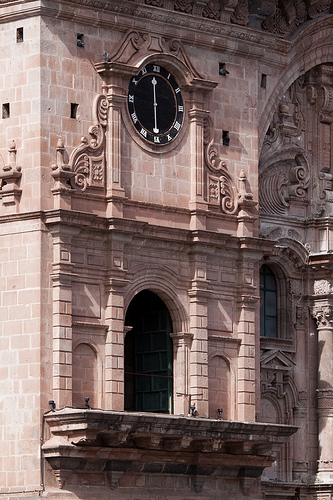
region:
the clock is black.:
[120, 58, 187, 148]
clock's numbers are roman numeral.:
[120, 59, 185, 143]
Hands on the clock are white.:
[119, 59, 192, 152]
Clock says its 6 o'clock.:
[120, 50, 188, 154]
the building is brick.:
[0, 1, 330, 496]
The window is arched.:
[109, 279, 197, 419]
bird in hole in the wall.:
[213, 59, 233, 78]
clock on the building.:
[104, 36, 211, 156]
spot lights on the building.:
[33, 391, 235, 427]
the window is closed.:
[253, 263, 286, 342]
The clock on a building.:
[125, 58, 190, 157]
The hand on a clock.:
[145, 71, 160, 101]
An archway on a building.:
[96, 265, 202, 415]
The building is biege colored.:
[0, 5, 328, 494]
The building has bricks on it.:
[4, 243, 32, 382]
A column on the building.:
[309, 306, 330, 471]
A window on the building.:
[253, 257, 296, 340]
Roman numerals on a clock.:
[120, 57, 197, 151]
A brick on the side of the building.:
[5, 328, 31, 350]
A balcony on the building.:
[38, 251, 305, 489]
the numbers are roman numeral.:
[121, 54, 188, 148]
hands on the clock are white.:
[146, 75, 165, 139]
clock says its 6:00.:
[120, 53, 189, 150]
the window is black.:
[252, 263, 287, 340]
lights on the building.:
[37, 390, 228, 423]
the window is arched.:
[111, 271, 195, 433]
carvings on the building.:
[261, 83, 311, 213]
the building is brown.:
[0, 1, 329, 494]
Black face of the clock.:
[92, 56, 205, 159]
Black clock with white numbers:
[109, 56, 209, 163]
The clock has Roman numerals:
[86, 31, 221, 168]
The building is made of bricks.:
[11, 4, 327, 489]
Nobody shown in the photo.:
[0, 5, 327, 494]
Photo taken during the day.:
[9, 10, 310, 495]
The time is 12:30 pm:
[100, 27, 217, 175]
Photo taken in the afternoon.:
[2, 0, 325, 491]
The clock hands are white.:
[111, 49, 197, 154]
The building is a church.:
[8, 0, 321, 495]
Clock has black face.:
[123, 86, 213, 161]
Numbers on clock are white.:
[112, 77, 191, 161]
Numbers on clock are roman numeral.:
[142, 60, 196, 126]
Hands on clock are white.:
[146, 78, 179, 150]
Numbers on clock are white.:
[136, 60, 222, 160]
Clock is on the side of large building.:
[114, 67, 263, 161]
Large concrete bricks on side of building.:
[15, 396, 186, 490]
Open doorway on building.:
[122, 383, 208, 422]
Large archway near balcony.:
[127, 289, 242, 377]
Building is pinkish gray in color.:
[15, 348, 109, 485]